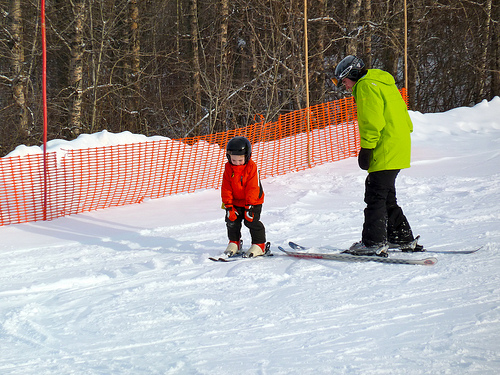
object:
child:
[221, 136, 271, 257]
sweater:
[221, 159, 265, 206]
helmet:
[226, 136, 252, 165]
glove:
[244, 205, 254, 222]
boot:
[249, 236, 265, 250]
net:
[41, 150, 87, 211]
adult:
[334, 55, 423, 256]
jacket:
[352, 69, 414, 173]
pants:
[362, 169, 414, 248]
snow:
[92, 272, 143, 308]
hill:
[331, 283, 385, 314]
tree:
[174, 3, 214, 133]